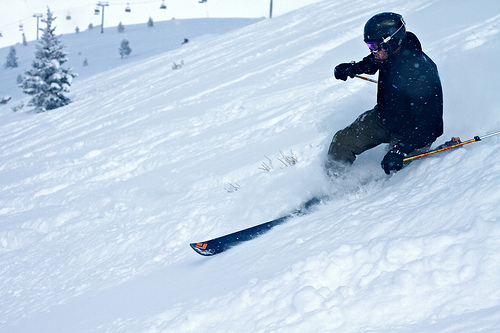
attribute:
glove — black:
[329, 59, 361, 87]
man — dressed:
[319, 18, 446, 208]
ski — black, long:
[177, 162, 389, 298]